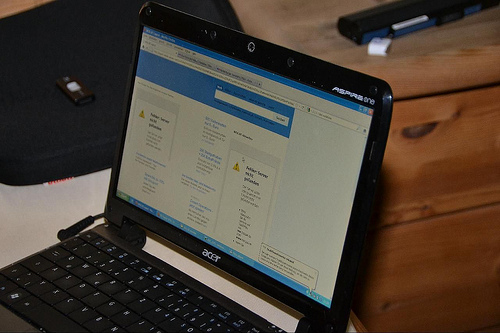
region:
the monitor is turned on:
[110, 19, 381, 311]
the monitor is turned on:
[103, 29, 383, 326]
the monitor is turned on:
[90, 19, 420, 304]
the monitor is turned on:
[81, 20, 371, 259]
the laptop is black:
[30, 21, 341, 332]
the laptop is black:
[74, 51, 351, 328]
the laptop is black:
[16, 40, 408, 320]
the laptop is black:
[25, 44, 340, 318]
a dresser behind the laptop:
[288, 18, 496, 328]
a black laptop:
[12, 7, 343, 328]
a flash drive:
[59, 70, 86, 108]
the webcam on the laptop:
[247, 42, 256, 49]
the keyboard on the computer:
[18, 241, 197, 328]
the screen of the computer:
[128, 25, 363, 295]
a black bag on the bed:
[7, 9, 207, 185]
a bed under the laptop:
[8, 16, 276, 326]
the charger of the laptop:
[51, 214, 105, 236]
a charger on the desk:
[338, 10, 458, 49]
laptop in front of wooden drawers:
[1, 1, 499, 331]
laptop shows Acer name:
[0, 0, 393, 331]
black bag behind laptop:
[1, 2, 396, 332]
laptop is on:
[1, 1, 397, 332]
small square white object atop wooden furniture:
[365, 34, 394, 56]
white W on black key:
[76, 260, 91, 273]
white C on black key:
[62, 293, 77, 308]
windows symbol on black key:
[5, 289, 25, 303]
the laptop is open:
[13, 7, 388, 328]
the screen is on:
[115, 22, 371, 305]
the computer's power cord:
[55, 210, 100, 239]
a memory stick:
[55, 74, 92, 106]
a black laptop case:
[0, 3, 233, 183]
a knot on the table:
[400, 118, 441, 136]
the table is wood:
[235, 3, 496, 330]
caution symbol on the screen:
[232, 158, 239, 172]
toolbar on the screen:
[115, 192, 330, 306]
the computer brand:
[202, 247, 219, 263]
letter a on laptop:
[198, 246, 208, 257]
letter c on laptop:
[206, 250, 213, 258]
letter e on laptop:
[211, 253, 218, 261]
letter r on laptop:
[211, 255, 223, 265]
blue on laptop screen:
[169, 64, 189, 92]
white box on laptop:
[238, 102, 256, 112]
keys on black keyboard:
[63, 255, 141, 311]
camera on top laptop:
[244, 36, 261, 56]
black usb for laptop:
[44, 64, 96, 111]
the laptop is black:
[0, 0, 394, 331]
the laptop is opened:
[1, 1, 392, 329]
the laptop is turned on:
[1, 1, 394, 331]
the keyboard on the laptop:
[1, 0, 395, 331]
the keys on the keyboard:
[0, 231, 282, 331]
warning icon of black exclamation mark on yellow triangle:
[228, 156, 244, 177]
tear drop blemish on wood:
[397, 102, 449, 145]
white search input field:
[210, 86, 295, 132]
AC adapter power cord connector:
[52, 209, 105, 241]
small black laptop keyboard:
[5, 230, 282, 330]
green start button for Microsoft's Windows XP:
[115, 187, 131, 202]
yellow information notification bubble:
[255, 239, 318, 297]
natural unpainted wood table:
[407, 66, 497, 326]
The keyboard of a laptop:
[2, 219, 287, 332]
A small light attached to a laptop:
[56, 206, 105, 242]